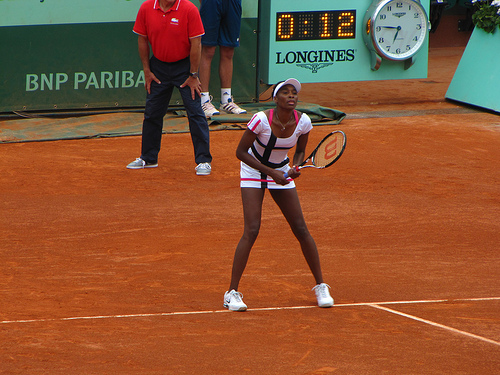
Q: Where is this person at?
A: Tennis match.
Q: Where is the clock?
A: Back right.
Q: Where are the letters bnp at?
A: Behind man in red.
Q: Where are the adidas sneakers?
A: On man in back right.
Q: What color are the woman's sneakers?
A: White.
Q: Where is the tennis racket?
A: Woman's hand.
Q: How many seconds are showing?
A: 12.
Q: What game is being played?
A: Tennis.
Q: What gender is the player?
A: Female.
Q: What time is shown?
A: 6:46.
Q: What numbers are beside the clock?
A: 0:12.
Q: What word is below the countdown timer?
A: LONGINES.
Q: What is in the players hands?
A: Tennis racket.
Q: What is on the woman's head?
A: Visor.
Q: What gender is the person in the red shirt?
A: Male.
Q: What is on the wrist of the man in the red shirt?
A: Watch.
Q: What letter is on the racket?
A: W.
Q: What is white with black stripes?
A: The outfit.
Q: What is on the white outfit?
A: Pink stripes.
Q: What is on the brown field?
A: White lines.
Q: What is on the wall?
A: Digital clock.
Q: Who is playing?
A: The athlete.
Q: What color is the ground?
A: Brown.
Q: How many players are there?
A: One.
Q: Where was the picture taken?
A: The tennis court.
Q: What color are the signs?
A: Teal.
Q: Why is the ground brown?
A: It is a clay court.